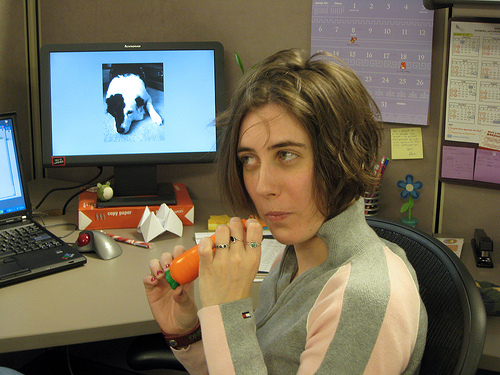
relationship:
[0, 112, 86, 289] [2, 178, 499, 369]
computer on desk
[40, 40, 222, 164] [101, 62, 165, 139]
screen has image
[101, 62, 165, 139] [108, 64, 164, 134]
image has dog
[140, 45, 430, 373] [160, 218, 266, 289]
woman holding carrot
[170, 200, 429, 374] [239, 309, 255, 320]
shirt has logo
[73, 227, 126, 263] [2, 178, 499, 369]
mouse on desk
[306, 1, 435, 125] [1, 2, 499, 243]
calendar on wall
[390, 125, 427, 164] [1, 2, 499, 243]
note on wall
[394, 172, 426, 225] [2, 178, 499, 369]
flower on desk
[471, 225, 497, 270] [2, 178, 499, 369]
stapler on desk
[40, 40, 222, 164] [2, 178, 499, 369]
screen on desk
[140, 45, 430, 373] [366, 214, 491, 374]
woman in chair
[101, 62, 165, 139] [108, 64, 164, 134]
image of dog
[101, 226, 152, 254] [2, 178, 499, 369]
pen on desk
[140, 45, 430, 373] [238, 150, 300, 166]
woman has eyes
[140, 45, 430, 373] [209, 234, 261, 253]
woman wearing rings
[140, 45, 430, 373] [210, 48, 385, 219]
woman has hair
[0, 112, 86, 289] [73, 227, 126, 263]
computer beside mouse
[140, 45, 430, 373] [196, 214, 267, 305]
woman has left hand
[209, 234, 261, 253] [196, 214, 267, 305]
rings are on left hand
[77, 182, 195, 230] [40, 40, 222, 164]
box beneath screen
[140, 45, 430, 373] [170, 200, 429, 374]
woman wearing shirt